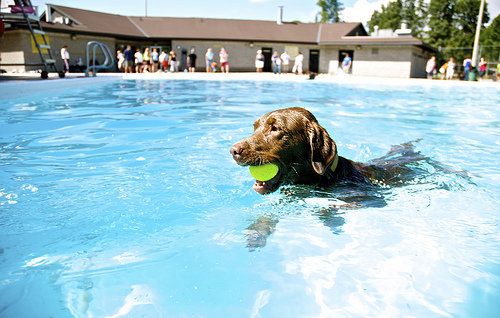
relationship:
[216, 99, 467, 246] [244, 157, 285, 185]
dog has ball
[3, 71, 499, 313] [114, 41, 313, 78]
water near people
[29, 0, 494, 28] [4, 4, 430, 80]
building below sky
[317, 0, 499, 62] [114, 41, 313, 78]
trees near people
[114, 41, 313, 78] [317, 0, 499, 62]
people near trees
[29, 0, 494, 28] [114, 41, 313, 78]
building near people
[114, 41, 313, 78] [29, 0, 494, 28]
people near building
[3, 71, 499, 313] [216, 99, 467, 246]
water around dog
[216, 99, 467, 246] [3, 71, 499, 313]
dog around water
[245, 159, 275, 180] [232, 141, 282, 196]
ball in mouth